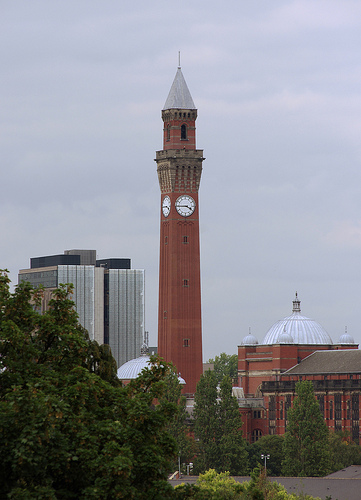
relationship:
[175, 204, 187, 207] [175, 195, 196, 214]
hand telling time on clock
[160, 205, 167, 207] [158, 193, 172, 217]
hand telling time on clock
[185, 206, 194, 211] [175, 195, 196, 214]
hand telling time on clock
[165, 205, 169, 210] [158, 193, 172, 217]
hand telling time on clock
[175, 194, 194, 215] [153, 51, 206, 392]
clock on building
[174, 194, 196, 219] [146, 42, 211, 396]
clock on building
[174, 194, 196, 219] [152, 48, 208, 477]
clock on building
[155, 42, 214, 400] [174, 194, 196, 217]
building on clock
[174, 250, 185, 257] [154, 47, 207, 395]
brick on tower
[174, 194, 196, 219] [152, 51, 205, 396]
clock on building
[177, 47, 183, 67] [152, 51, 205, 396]
pole on building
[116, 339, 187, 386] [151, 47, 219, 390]
dome near tower